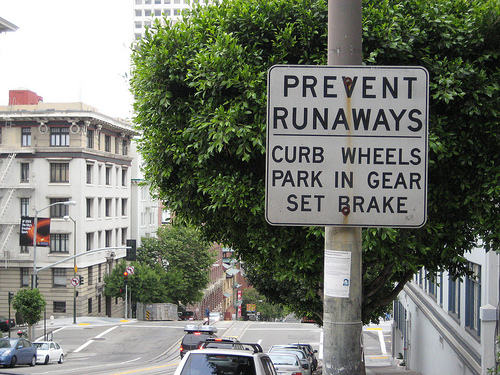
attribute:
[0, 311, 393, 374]
street — in view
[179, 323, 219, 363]
vehicle — moving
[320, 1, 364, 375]
pole — gray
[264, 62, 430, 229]
sign — black, white, warning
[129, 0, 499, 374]
tree — green, thick, leafy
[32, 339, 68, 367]
car — parked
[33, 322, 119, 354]
line — for crosswalk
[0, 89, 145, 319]
building — on the left, gray, multi-story, high rise, old in appearance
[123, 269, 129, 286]
traffic signal — red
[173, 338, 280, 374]
vehicle — parked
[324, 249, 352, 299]
paper — attached to pole, white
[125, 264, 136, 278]
sign — black, red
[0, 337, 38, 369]
vehicle — blue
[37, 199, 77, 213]
street lamp — gray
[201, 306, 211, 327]
person — walking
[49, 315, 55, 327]
fire hydrant — white